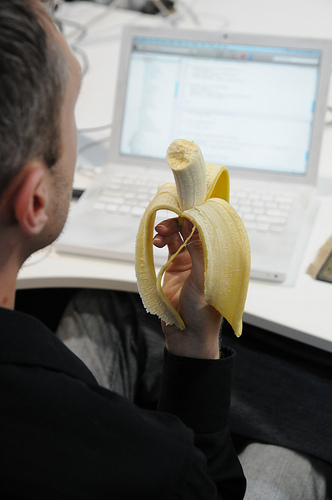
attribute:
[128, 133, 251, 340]
banana — half-eaten, yellow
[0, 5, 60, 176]
hair — black, grey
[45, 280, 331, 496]
pants — gray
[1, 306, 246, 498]
shirt — black, dress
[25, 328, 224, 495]
suit — black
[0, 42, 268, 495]
man — grown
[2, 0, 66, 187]
hair — salt and pepper